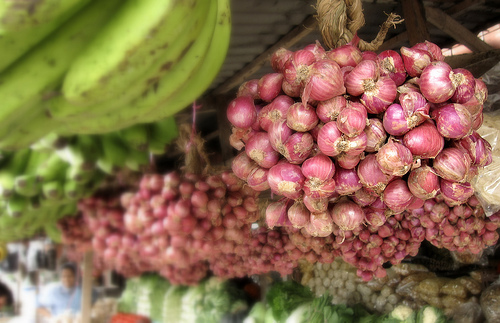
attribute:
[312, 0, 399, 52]
rope — brown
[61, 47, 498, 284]
onions — pink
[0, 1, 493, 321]
market — fruit, vegetable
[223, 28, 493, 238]
onions — pink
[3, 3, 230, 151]
plantains — green, black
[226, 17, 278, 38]
roof — metal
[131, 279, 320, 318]
bags — more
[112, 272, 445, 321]
celery — green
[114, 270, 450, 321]
lettuce — green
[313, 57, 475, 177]
onions — pink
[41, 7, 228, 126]
banana — green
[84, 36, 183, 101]
spots — brown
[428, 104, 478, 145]
onion — pink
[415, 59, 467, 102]
onion — pink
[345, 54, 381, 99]
onion — pink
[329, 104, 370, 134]
onion — pink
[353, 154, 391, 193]
onion — pink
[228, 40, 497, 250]
onions — red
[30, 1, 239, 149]
plantains — are not ripe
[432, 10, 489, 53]
support beam — brown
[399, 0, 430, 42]
support beam — brown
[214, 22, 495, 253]
onions — red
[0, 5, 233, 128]
bananas — green